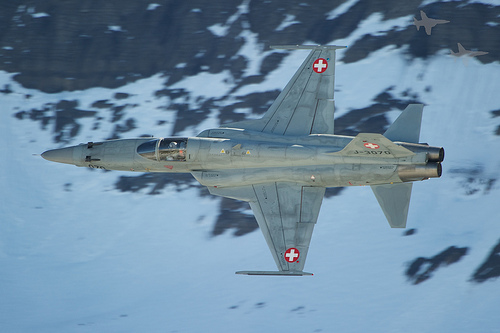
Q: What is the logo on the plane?
A: White crosses.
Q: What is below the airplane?
A: Snow.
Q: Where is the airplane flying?
A: In the mountains.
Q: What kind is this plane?
A: A jet.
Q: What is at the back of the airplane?
A: The tail.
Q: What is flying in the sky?
A: A plane.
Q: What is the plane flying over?
A: Mountains.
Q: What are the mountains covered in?
A: Snow.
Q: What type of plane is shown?
A: Military.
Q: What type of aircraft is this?
A: Jet.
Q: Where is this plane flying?
A: Sky.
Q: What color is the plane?
A: Grey.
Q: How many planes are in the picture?
A: 3.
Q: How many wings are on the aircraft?
A: 4.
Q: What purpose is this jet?
A: Medical.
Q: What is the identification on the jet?
A: J-3070.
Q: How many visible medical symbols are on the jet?
A: 3.